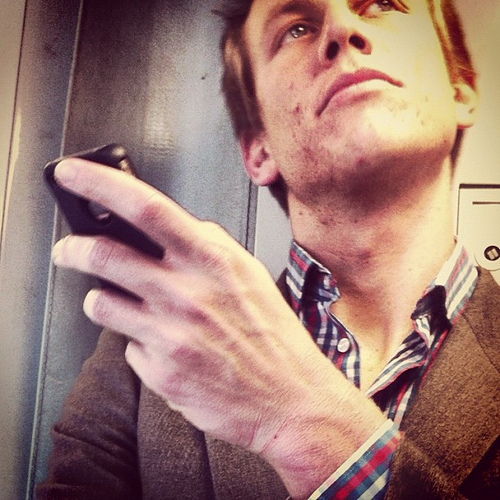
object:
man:
[23, 0, 500, 498]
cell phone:
[41, 142, 167, 296]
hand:
[50, 155, 314, 445]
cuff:
[250, 419, 437, 497]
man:
[29, 7, 500, 499]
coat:
[35, 268, 500, 498]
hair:
[212, 2, 267, 133]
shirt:
[278, 240, 483, 498]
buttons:
[337, 332, 352, 356]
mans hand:
[50, 155, 326, 459]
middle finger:
[53, 234, 172, 299]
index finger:
[53, 155, 210, 252]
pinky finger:
[124, 336, 163, 398]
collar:
[284, 231, 480, 330]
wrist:
[260, 377, 397, 487]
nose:
[315, 0, 374, 67]